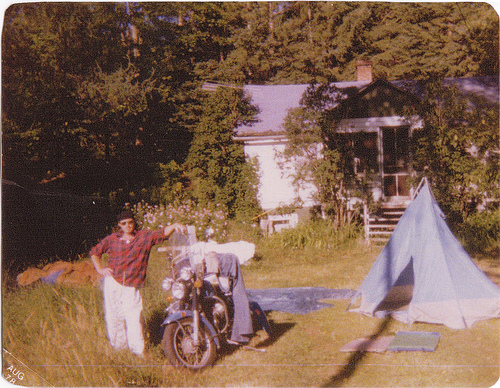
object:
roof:
[202, 78, 500, 141]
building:
[202, 60, 500, 234]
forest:
[5, 1, 498, 248]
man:
[89, 211, 187, 355]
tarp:
[247, 266, 361, 286]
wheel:
[161, 310, 217, 374]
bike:
[157, 225, 256, 374]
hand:
[150, 222, 186, 245]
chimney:
[354, 57, 373, 80]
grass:
[7, 297, 106, 382]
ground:
[2, 239, 499, 387]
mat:
[339, 335, 394, 353]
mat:
[388, 331, 440, 352]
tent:
[344, 177, 500, 329]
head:
[117, 210, 137, 234]